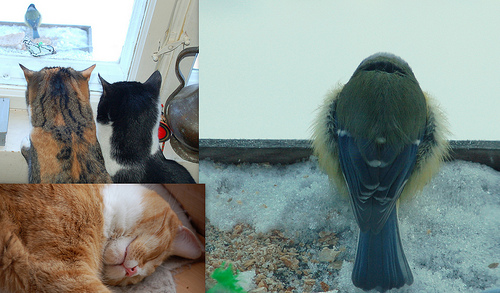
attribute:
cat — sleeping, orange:
[1, 184, 204, 291]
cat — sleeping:
[6, 189, 204, 287]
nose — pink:
[121, 258, 146, 285]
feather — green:
[211, 261, 239, 291]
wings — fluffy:
[320, 87, 352, 187]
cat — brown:
[21, 64, 97, 182]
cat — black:
[95, 72, 196, 182]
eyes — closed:
[122, 250, 158, 290]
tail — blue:
[353, 194, 412, 291]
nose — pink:
[115, 256, 140, 282]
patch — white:
[93, 184, 138, 243]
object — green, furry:
[210, 261, 245, 288]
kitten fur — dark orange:
[39, 203, 88, 254]